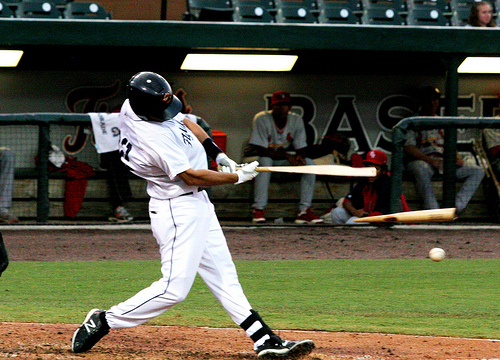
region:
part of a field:
[358, 295, 380, 340]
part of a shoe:
[294, 348, 299, 353]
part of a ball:
[434, 231, 449, 260]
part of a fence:
[55, 193, 67, 204]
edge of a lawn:
[342, 280, 362, 310]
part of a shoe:
[297, 342, 302, 349]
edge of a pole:
[400, 166, 425, 196]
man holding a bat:
[65, 66, 380, 356]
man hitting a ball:
[43, 51, 463, 357]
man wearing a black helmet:
[27, 53, 378, 358]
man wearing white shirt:
[63, 51, 315, 357]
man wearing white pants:
[65, 60, 310, 357]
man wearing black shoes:
[56, 62, 332, 357]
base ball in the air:
[405, 237, 460, 265]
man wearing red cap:
[245, 85, 323, 166]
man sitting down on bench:
[251, 80, 306, 160]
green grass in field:
[343, 260, 408, 310]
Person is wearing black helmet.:
[138, 63, 178, 119]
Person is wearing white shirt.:
[117, 121, 204, 179]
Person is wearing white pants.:
[128, 212, 276, 317]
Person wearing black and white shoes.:
[56, 307, 163, 357]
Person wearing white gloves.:
[221, 155, 267, 195]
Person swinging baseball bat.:
[202, 138, 321, 208]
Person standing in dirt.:
[72, 288, 357, 352]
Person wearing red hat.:
[266, 85, 307, 106]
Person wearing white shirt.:
[251, 112, 321, 157]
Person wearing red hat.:
[353, 145, 396, 187]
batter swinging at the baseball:
[66, 67, 326, 359]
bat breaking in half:
[240, 151, 458, 230]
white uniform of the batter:
[88, 109, 248, 323]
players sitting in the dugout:
[233, 82, 494, 219]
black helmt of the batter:
[126, 70, 179, 123]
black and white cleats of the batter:
[73, 304, 317, 358]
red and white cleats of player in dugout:
[249, 202, 329, 226]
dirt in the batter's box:
[1, 316, 488, 358]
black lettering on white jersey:
[117, 136, 131, 163]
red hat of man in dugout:
[266, 87, 296, 108]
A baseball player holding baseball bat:
[71, 69, 315, 357]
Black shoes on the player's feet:
[72, 307, 313, 359]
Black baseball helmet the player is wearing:
[126, 70, 179, 122]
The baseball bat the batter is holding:
[219, 163, 377, 175]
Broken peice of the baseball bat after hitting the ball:
[355, 208, 455, 225]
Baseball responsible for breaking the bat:
[429, 247, 445, 259]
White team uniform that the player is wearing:
[106, 97, 267, 341]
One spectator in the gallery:
[474, 0, 495, 30]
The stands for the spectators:
[0, 2, 498, 26]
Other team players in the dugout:
[100, 92, 498, 220]